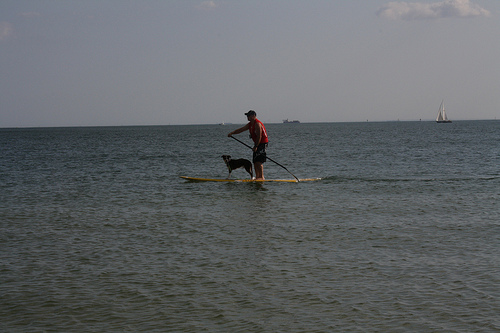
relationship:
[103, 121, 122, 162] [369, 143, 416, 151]
water with ripples